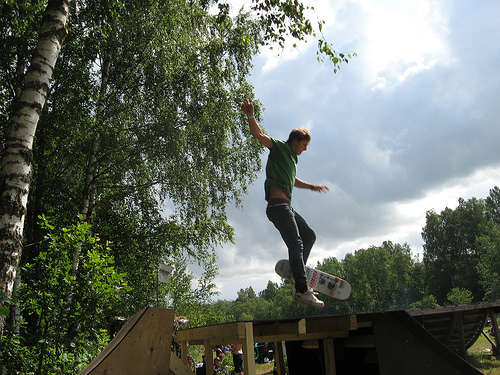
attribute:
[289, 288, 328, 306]
shoes — white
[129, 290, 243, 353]
ramp — wood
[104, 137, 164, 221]
leaves — green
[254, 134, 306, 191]
shirt — green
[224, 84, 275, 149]
arm — stretched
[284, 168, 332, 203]
arm — stretched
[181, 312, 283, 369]
people — gathered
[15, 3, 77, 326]
tree trunk — large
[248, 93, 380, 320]
skateboarder — airborne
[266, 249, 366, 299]
skateboard — white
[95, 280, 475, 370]
ramp — wood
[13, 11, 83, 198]
trunk — white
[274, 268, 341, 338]
sneaker — white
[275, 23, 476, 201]
clouds — dark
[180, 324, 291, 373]
people — sitting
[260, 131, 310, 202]
shirt — green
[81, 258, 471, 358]
ramp — wood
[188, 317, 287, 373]
people — distant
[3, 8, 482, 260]
sky — cloudy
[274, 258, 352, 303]
wheels — yellow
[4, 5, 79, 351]
tree — big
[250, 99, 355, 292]
person — airborne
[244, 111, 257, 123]
watch — silver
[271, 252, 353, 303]
skateboard — airborne, white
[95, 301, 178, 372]
skateboard ramp — wooden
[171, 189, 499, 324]
trees — green, tall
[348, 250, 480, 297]
leaves — green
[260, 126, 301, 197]
shirt — short, green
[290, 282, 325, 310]
sport shoe — white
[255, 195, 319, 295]
pants — grey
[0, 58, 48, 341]
tree trunk — white, black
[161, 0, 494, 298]
sky — grey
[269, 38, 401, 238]
clouds — white